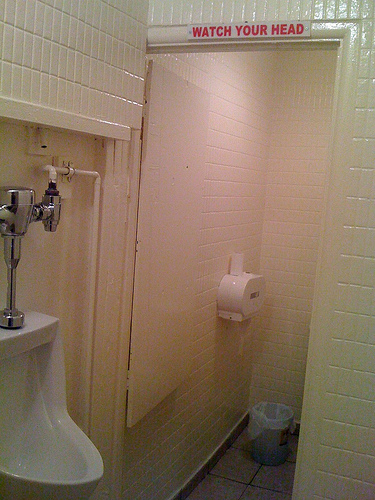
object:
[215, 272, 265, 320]
toilet paper holder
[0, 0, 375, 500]
waste can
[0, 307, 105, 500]
urinal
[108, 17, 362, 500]
stall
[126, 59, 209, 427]
door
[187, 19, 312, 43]
sign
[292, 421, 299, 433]
label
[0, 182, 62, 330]
fixture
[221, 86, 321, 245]
part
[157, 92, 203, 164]
section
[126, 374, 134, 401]
hinge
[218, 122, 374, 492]
wall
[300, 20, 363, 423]
edge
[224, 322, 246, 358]
tissue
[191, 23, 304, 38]
notice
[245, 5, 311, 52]
part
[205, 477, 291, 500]
floor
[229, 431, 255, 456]
part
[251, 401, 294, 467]
bin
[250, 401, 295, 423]
edge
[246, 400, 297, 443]
bag liner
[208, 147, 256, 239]
tile wall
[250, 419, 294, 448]
roll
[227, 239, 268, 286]
toilet paper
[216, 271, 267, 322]
holder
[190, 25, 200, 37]
"w"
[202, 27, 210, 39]
"a"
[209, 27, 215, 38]
"t"